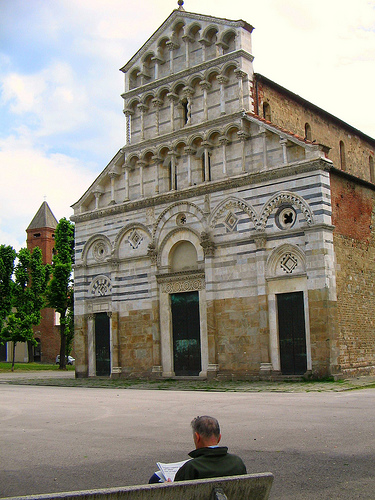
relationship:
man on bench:
[152, 426, 279, 489] [94, 480, 292, 499]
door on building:
[156, 274, 236, 399] [1, 39, 369, 390]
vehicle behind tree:
[43, 340, 76, 369] [37, 220, 82, 383]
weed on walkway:
[129, 369, 154, 391] [46, 352, 324, 392]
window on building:
[61, 170, 350, 282] [1, 39, 369, 390]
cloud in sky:
[8, 10, 113, 71] [21, 34, 141, 176]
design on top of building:
[94, 2, 259, 160] [1, 39, 369, 390]